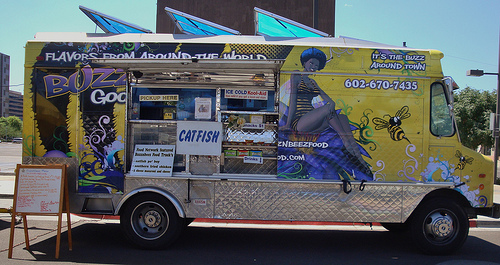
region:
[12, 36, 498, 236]
a yellow vendor truck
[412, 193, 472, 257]
a black wheel on a truck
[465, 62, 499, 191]
a street lamp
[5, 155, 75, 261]
a white menu board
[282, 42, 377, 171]
a woman in a yellow and black striped swimsuit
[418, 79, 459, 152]
a side window on a vendor truck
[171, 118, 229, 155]
a white sign with blue writing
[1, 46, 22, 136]
a building behind a van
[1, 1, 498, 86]
a pale blue sky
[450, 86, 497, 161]
trees behind a bus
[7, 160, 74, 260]
White erase board next to truck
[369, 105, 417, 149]
Large bee on truck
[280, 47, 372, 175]
Black woman painted on truck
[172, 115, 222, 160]
CATFISH sign on truck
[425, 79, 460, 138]
Small window on truck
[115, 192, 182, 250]
Black rubber tire on truck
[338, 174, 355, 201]
Black strap dangling on side of truck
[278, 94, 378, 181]
Flower painted below woman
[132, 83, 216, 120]
Window on truck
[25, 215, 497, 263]
Shadow of truck on ground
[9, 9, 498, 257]
food truck parked on sidewalk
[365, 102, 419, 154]
cartoon bumble bee character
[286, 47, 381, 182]
female character painted on truck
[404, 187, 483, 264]
black truck tire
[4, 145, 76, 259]
easel with whiteboard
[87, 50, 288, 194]
serving window on food truck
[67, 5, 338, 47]
three vents in truck roof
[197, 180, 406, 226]
embossed stainless steel panel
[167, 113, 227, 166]
white sign with blue writing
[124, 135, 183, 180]
white sign with black writing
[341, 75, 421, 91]
phone number on a yellow lunch truck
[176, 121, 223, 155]
white sign reading CATFISH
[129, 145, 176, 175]
white and black sign on a lunch truck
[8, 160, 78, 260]
easel board with red marker writing on it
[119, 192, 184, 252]
black truck wheel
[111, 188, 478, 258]
two black truck wheels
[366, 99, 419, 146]
bee graphic on a yellow food truck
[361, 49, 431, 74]
slogan on a yellow luch truck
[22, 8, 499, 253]
yellow heavily designed lunch truck parked on a street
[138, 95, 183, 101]
white pickup sign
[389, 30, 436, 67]
the sky is white and blue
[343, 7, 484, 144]
the sky is white and blue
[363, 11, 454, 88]
the sky is white and blue